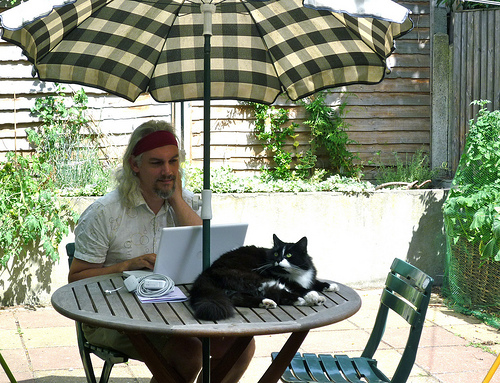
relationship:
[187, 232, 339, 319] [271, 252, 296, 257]
cat has eyes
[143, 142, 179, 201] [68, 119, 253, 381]
face of man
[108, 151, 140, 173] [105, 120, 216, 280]
ear of man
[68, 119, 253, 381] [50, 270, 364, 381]
man sitting at outdoor table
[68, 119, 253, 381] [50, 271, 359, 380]
man sitting at outdoor table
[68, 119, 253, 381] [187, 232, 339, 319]
man with a cat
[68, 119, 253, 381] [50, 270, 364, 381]
man sharing outdoor table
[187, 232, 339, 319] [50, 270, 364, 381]
cat sharing outdoor table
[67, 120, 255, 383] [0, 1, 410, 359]
man sitting under umbrella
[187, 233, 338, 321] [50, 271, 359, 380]
cat sitting on outdoor table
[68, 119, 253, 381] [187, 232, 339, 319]
man sitting near cat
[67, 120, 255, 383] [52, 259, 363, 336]
man at table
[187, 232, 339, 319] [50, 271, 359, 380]
cat on outdoor table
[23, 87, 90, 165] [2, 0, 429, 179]
ivy on wall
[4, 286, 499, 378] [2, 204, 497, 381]
pavers for patio